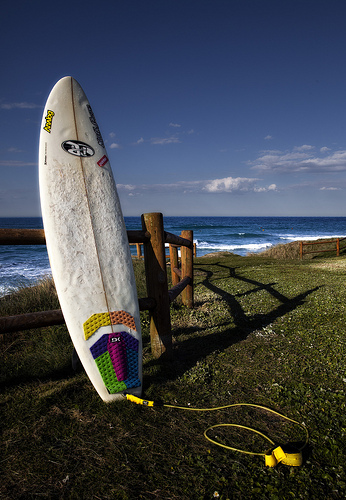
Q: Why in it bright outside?
A: It's daytime.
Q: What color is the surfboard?
A: White.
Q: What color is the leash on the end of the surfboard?
A: Yellow.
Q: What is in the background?
A: Ocean.